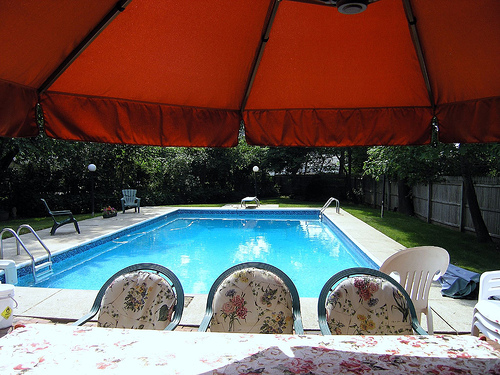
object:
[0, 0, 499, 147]
umbrella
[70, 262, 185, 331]
chairs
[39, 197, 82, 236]
chair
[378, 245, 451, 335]
chair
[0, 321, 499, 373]
table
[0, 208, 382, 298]
pool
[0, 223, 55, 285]
ladder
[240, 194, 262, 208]
board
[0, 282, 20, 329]
bucket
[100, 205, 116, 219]
plant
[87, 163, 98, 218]
pole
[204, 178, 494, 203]
fence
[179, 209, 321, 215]
tile